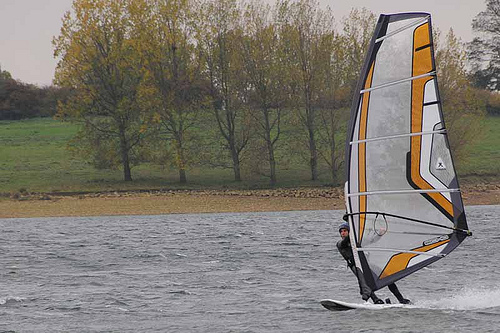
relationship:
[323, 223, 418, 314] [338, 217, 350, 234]
man with helmet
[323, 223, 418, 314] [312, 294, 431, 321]
man with surf board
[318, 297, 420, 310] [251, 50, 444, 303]
surfboard with man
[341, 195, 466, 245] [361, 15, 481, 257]
cord with parasail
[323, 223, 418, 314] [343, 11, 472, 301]
man with sail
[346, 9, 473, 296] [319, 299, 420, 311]
sail with surfboard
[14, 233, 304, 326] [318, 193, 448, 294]
water with man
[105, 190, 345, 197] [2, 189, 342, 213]
rocks on beach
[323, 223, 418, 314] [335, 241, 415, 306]
man in swim suit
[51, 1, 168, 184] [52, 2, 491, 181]
tree in woods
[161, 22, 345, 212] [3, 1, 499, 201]
tree in woods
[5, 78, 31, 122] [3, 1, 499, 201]
tree in woods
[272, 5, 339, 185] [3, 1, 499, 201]
tree in woods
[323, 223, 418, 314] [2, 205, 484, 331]
man boarding on water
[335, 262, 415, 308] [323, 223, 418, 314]
pants on man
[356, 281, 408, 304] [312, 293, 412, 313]
feet on surfboard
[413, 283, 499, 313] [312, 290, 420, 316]
splash from surfboard